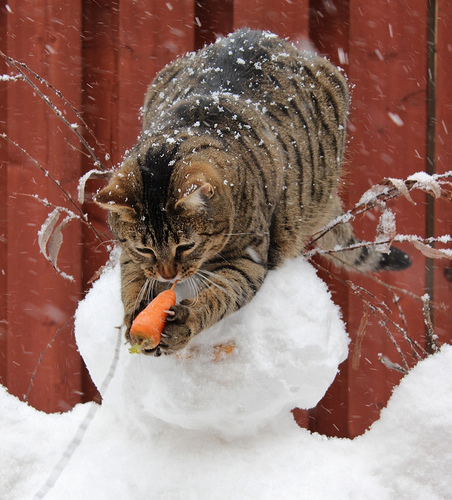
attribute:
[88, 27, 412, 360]
cat — stripped, tiger striped, fat, determined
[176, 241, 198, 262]
eye — righ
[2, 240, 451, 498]
snowman — snow, defaced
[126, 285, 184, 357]
carrot — small, orange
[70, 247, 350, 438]
snowball — head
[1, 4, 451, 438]
wall — red, wood, wide board fencing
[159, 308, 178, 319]
claw — sharp, extended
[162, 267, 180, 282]
nose — brown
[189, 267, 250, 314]
whiskers — white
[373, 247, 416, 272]
tip — dark, black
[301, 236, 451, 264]
branch — bare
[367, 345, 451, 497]
arm — snow